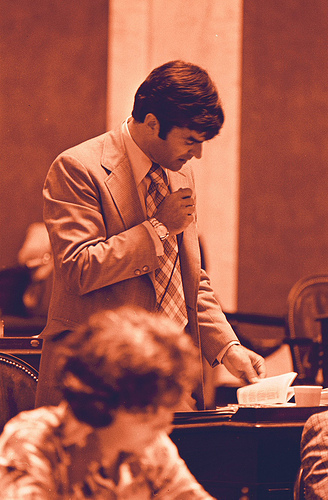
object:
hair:
[130, 57, 226, 143]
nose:
[190, 139, 204, 163]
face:
[159, 120, 210, 173]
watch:
[147, 216, 172, 244]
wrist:
[148, 213, 171, 247]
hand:
[221, 341, 267, 388]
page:
[234, 368, 298, 406]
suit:
[36, 119, 242, 410]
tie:
[143, 164, 190, 336]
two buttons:
[130, 261, 153, 277]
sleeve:
[66, 212, 166, 292]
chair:
[1, 349, 40, 437]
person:
[0, 305, 224, 499]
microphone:
[177, 186, 193, 216]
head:
[130, 57, 225, 174]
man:
[30, 56, 268, 435]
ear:
[143, 112, 157, 142]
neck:
[124, 114, 162, 170]